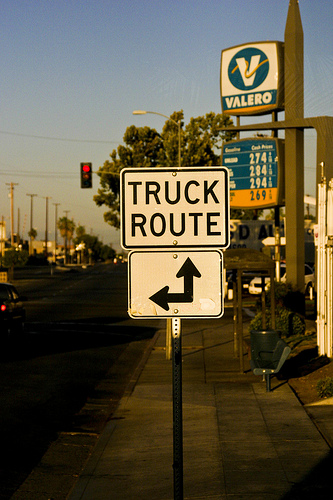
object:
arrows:
[149, 257, 202, 312]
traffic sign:
[126, 248, 224, 321]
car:
[0, 282, 28, 337]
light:
[1, 304, 6, 312]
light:
[82, 164, 90, 173]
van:
[248, 258, 315, 298]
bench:
[249, 337, 292, 392]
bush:
[248, 305, 306, 342]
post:
[133, 107, 183, 167]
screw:
[172, 240, 178, 246]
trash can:
[251, 327, 280, 377]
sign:
[220, 40, 285, 116]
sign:
[120, 166, 231, 252]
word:
[224, 90, 271, 109]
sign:
[221, 137, 285, 209]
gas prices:
[251, 143, 274, 152]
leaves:
[123, 124, 163, 166]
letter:
[184, 180, 200, 204]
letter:
[204, 180, 220, 204]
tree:
[94, 109, 239, 240]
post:
[172, 317, 184, 499]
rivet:
[173, 253, 178, 259]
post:
[265, 376, 271, 392]